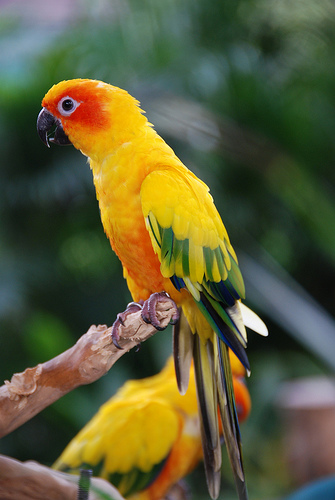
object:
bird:
[36, 75, 268, 497]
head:
[35, 78, 124, 150]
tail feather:
[171, 299, 267, 500]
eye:
[57, 93, 81, 117]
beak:
[33, 108, 67, 150]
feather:
[96, 119, 269, 499]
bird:
[49, 335, 253, 498]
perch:
[1, 291, 174, 446]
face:
[224, 351, 250, 396]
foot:
[141, 290, 179, 329]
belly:
[102, 223, 180, 298]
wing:
[140, 169, 254, 377]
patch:
[44, 81, 113, 134]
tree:
[2, 3, 335, 500]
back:
[145, 115, 228, 241]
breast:
[82, 152, 146, 225]